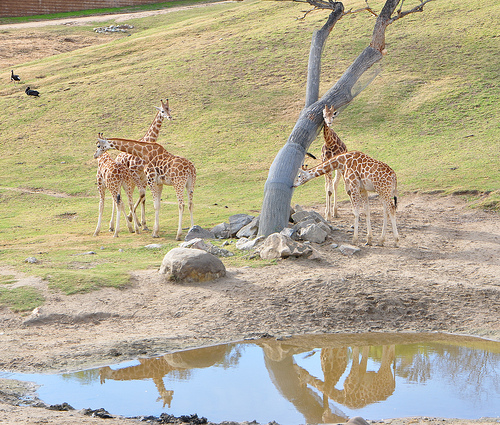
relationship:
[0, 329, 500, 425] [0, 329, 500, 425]
pond of pond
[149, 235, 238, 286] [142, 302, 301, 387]
rock near pond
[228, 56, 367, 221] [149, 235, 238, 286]
tree near rock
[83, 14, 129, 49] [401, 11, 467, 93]
plant on hill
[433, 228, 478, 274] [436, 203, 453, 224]
patch of dirt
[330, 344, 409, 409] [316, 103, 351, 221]
reflection of giraffes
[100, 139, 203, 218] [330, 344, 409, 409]
giraffe's brown reflection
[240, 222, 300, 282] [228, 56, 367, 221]
rocks around tree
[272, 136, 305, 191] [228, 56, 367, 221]
section of tree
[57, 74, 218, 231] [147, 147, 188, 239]
three giraffe standing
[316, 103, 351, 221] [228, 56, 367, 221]
giraffes next to tree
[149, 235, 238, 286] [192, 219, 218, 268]
rock sticking out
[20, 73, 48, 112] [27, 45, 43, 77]
birds in background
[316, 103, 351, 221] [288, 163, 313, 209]
giraffes with head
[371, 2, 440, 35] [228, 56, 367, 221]
branches of tree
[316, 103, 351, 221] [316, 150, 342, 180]
giraffes rubbing neck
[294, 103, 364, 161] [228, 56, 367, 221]
giraffes close to tree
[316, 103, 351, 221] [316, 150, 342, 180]
giraffes has neck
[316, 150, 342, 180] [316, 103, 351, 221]
neck of giraffes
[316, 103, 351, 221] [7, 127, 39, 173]
giraffes facing left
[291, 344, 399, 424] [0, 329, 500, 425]
reflection in pond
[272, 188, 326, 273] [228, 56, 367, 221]
stone near tree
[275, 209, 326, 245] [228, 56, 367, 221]
stones surround tree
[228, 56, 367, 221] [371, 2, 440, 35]
tree without leaves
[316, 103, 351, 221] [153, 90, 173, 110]
giraffes has horns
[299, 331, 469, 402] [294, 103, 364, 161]
waterhole next to giraffes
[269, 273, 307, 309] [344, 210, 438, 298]
sand on ground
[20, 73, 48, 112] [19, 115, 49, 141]
birds on grass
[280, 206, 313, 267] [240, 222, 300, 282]
pile of rocks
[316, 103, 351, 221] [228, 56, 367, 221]
giraffes licking tree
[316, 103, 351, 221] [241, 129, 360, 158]
giraffes scratching itself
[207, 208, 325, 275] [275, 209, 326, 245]
circle of stones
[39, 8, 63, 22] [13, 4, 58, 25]
red brick wall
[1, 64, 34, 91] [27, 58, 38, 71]
ostrich gallivanting distance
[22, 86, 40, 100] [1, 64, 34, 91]
birds sits beside ostrich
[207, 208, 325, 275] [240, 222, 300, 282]
circle of rocks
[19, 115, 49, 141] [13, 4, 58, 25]
grass beside wall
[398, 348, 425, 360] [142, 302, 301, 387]
grasses reflected in pond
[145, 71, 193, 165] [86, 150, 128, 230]
big and smaller giraffe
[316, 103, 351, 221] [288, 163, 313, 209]
giraffes has head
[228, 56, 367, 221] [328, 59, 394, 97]
tree wears wire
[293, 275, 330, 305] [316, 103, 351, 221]
footprints of giraffes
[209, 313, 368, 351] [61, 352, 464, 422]
shoreline across pond